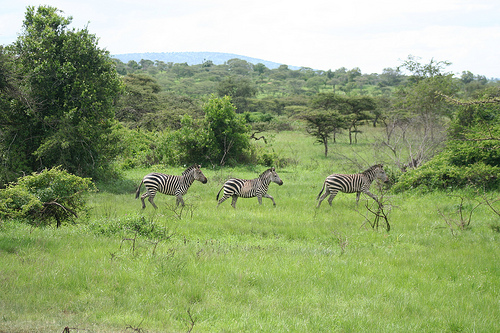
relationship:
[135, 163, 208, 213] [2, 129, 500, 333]
zebra in grass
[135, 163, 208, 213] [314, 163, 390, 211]
zebra chasing zebra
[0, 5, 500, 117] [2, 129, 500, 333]
forest surrounding grass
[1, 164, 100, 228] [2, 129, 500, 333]
bush on grass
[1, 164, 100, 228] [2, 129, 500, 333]
bush in grass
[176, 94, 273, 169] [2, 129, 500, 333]
bush in grass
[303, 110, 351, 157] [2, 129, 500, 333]
tree in grass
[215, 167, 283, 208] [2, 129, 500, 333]
zebra in grass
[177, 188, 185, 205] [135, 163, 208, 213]
front leg of zebra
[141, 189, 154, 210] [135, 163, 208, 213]
back leg of zebra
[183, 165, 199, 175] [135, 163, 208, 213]
mane of zebra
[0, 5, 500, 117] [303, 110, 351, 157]
forest behind tree